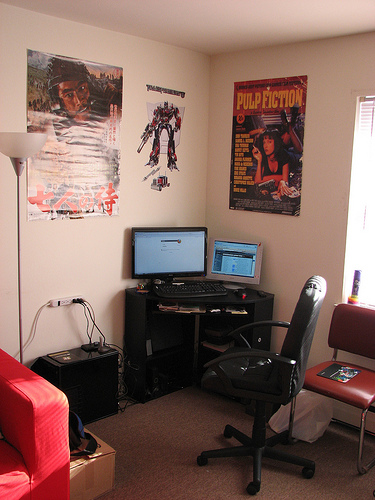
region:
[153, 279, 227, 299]
a black computer keyboard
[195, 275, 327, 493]
a black rolling chair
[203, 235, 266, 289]
a small computer monitor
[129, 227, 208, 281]
a black computer monitor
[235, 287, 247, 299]
a black computer mouse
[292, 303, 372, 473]
a small red chair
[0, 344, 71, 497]
a plush red chair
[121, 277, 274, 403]
a black corner desk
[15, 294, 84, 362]
an electric bar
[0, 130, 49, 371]
a metal floor lamp with shade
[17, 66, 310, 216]
posters on the wall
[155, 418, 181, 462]
the floor is carpet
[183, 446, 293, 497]
wheels on the chair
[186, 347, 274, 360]
arm of the chair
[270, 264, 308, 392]
back of the chear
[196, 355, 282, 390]
seat of the chair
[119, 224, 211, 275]
the monitor is on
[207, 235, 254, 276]
the monitor is on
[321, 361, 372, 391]
the chair is red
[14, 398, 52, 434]
the couch is red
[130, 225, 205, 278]
the monitor is turned on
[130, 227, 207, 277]
the monitor has a black frame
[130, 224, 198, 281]
the monitor is on a desk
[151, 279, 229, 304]
the keyboard is on the desk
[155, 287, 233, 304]
the keyboard is black in color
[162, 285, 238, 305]
the keyboard is made of plastic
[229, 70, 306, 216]
a poster is on the wall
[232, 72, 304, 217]
the poster is for a movie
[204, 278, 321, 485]
an office chair is in the room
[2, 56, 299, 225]
posters on the wall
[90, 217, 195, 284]
monitor on the shelf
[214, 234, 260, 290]
monitor on the shelf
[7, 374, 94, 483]
the couch is red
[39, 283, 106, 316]
plugs on the wall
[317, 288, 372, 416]
the chair is red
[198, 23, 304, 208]
poster for pulp fiction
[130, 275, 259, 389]
he shelf is black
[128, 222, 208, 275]
computer monitor on the stand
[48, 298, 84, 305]
power strip on the wall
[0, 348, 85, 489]
A red couch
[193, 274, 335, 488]
The black office chair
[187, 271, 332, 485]
The black office chair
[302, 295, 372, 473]
The red chair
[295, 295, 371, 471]
A red chair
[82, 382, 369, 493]
The brown carpet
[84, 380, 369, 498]
A brown carpet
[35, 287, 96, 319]
The surge protector on the wall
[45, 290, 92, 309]
A surge protector on the wall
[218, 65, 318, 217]
pulp fiction movie poster on wall